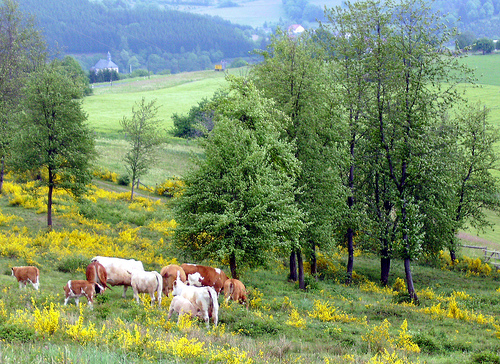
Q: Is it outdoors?
A: Yes, it is outdoors.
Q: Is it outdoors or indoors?
A: It is outdoors.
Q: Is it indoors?
A: No, it is outdoors.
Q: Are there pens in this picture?
A: No, there are no pens.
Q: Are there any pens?
A: No, there are no pens.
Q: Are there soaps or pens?
A: No, there are no pens or soaps.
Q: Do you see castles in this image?
A: No, there are no castles.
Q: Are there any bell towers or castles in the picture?
A: No, there are no castles or bell towers.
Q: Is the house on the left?
A: Yes, the house is on the left of the image.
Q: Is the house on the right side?
A: No, the house is on the left of the image.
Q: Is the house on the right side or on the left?
A: The house is on the left of the image.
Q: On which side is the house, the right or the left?
A: The house is on the left of the image.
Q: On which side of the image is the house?
A: The house is on the left of the image.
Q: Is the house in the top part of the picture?
A: Yes, the house is in the top of the image.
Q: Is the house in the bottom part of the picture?
A: No, the house is in the top of the image.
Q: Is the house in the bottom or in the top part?
A: The house is in the top of the image.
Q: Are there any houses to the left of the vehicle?
A: Yes, there is a house to the left of the vehicle.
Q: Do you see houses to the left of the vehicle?
A: Yes, there is a house to the left of the vehicle.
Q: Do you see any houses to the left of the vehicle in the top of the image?
A: Yes, there is a house to the left of the vehicle.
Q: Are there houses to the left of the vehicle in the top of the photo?
A: Yes, there is a house to the left of the vehicle.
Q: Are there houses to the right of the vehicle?
A: No, the house is to the left of the vehicle.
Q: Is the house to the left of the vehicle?
A: Yes, the house is to the left of the vehicle.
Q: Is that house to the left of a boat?
A: No, the house is to the left of the vehicle.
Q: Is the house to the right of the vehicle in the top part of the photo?
A: No, the house is to the left of the vehicle.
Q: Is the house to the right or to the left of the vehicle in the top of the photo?
A: The house is to the left of the vehicle.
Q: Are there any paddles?
A: No, there are no paddles.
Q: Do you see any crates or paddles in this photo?
A: No, there are no paddles or crates.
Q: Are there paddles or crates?
A: No, there are no paddles or crates.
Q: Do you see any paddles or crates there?
A: No, there are no paddles or crates.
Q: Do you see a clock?
A: No, there are no clocks.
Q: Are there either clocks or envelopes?
A: No, there are no clocks or envelopes.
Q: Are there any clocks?
A: No, there are no clocks.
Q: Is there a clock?
A: No, there are no clocks.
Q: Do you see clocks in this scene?
A: No, there are no clocks.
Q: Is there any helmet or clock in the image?
A: No, there are no clocks or helmets.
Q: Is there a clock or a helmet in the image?
A: No, there are no clocks or helmets.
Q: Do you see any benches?
A: No, there are no benches.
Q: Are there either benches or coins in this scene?
A: No, there are no benches or coins.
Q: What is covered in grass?
A: The hill side is covered in grass.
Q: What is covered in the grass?
A: The hill side is covered in grass.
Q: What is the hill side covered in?
A: The hill side is covered in grass.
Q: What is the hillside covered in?
A: The hill side is covered in grass.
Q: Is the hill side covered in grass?
A: Yes, the hill side is covered in grass.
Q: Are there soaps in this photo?
A: No, there are no soaps.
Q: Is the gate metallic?
A: Yes, the gate is metallic.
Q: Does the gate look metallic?
A: Yes, the gate is metallic.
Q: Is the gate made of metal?
A: Yes, the gate is made of metal.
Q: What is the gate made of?
A: The gate is made of metal.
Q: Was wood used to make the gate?
A: No, the gate is made of metal.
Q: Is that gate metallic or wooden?
A: The gate is metallic.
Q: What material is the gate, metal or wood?
A: The gate is made of metal.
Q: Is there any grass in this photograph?
A: Yes, there is grass.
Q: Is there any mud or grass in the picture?
A: Yes, there is grass.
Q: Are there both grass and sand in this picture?
A: No, there is grass but no sand.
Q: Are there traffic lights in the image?
A: No, there are no traffic lights.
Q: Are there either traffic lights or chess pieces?
A: No, there are no traffic lights or chess pieces.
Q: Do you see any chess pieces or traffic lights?
A: No, there are no traffic lights or chess pieces.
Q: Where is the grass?
A: The grass is on the ground.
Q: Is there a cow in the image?
A: Yes, there is a cow.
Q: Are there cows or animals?
A: Yes, there is a cow.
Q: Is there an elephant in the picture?
A: No, there are no elephants.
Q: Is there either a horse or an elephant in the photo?
A: No, there are no elephants or horses.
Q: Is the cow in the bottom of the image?
A: Yes, the cow is in the bottom of the image.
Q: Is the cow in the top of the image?
A: No, the cow is in the bottom of the image.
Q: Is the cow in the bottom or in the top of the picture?
A: The cow is in the bottom of the image.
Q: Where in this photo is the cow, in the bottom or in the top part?
A: The cow is in the bottom of the image.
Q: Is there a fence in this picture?
A: Yes, there is a fence.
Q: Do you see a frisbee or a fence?
A: Yes, there is a fence.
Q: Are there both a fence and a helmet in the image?
A: No, there is a fence but no helmets.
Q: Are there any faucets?
A: No, there are no faucets.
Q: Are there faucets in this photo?
A: No, there are no faucets.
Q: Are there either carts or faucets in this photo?
A: No, there are no faucets or carts.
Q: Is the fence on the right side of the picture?
A: Yes, the fence is on the right of the image.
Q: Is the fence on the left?
A: No, the fence is on the right of the image.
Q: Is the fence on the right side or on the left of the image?
A: The fence is on the right of the image.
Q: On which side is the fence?
A: The fence is on the right of the image.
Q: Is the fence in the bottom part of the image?
A: Yes, the fence is in the bottom of the image.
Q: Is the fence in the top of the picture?
A: No, the fence is in the bottom of the image.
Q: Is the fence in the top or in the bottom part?
A: The fence is in the bottom of the image.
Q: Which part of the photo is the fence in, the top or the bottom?
A: The fence is in the bottom of the image.